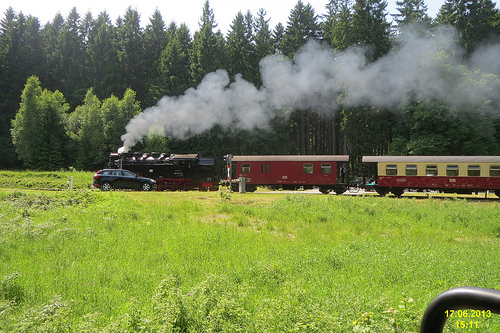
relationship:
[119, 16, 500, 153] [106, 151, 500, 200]
smoke from train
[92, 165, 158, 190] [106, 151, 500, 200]
car beside train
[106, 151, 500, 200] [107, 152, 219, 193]
train has engine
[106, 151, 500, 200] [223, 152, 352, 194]
train has passenger car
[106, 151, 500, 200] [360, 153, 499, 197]
train has passenger car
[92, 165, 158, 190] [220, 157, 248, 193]
car at railroad signal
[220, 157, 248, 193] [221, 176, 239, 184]
railroad signal has arm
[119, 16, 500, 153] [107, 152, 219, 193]
smoke from engine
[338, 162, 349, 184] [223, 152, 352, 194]
conductor on passenger car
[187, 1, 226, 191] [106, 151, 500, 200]
tree behind train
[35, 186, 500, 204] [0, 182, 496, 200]
road beside track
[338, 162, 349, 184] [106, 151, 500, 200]
conductor standing on train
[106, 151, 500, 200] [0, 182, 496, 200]
train on track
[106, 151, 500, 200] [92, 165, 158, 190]
train beside car